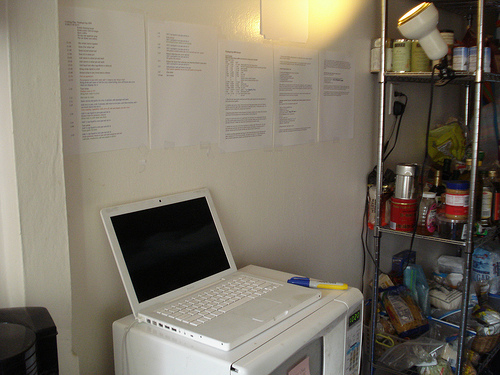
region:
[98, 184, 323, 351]
a white laptop computer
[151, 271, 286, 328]
a white keyboard on the laptop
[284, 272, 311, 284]
a blue marker lid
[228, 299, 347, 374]
the door of a microwave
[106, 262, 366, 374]
a white microwave under the laptop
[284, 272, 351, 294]
a large marker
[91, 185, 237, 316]
a white laptop monitor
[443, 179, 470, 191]
a blue jar lid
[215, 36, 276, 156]
a piece of paper on the wall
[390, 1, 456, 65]
a light on the rack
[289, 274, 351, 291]
A yellow highlighter with a blue cap.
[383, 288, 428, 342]
Dry pasta noodles in a bag.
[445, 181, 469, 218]
A jar of peanut butter.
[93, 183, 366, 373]
A laptop on a microwave.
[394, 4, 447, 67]
A small flood light, turned on.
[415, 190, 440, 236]
A jar of sauce, 1/3rd full.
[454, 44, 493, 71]
Several cans on the top shelf.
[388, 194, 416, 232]
A red can of coffee.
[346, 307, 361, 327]
The digital microwave time display, reading 10:20.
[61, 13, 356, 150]
Papers posted on the wall.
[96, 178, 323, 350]
Laptop computer sitting on top of microwave oven.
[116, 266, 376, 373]
A white microwave oven.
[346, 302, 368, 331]
Timer display on front of microwave oven.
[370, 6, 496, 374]
Rack used for food storage.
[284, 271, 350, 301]
Yellow and blue pen lying on microwave oven.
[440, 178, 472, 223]
Jar of peanut butter sitting on rack.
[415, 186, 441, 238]
Bottle of honey sitting on rack.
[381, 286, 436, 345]
Bag of pasta lying on rack.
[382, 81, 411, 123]
Power outlet mounted on wall.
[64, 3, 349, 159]
Papers taped to wall.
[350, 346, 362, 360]
edge of a micro wave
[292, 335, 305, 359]
top of a micro wave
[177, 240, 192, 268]
screen of a lap top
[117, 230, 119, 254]
edge of a lap top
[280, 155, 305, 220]
part of a white wall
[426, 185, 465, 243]
section of food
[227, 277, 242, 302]
key pad of a laptop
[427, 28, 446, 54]
lower part of a bulb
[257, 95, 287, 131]
paper on the wall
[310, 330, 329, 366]
door of the micro wave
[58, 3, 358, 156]
lists of typewritten information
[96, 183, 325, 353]
open lap top computer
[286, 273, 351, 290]
two felt tip markers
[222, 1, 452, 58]
light shining on wall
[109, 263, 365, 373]
white microwave oven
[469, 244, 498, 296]
sack of granulated sugar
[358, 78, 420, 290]
electrical outlet with plugs and cords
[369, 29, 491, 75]
several cans of food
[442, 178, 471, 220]
jar of peanut butter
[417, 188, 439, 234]
container of jelly